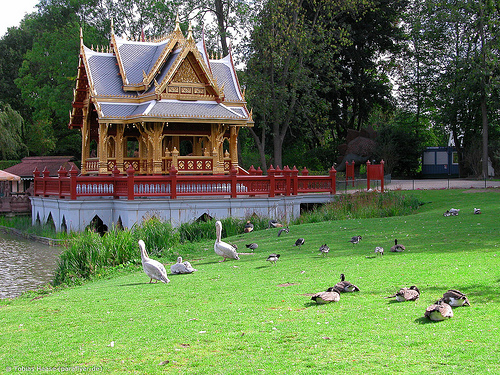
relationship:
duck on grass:
[306, 230, 430, 333] [245, 203, 476, 369]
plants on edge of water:
[49, 230, 144, 278] [14, 241, 62, 270]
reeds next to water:
[5, 264, 46, 300] [14, 241, 62, 270]